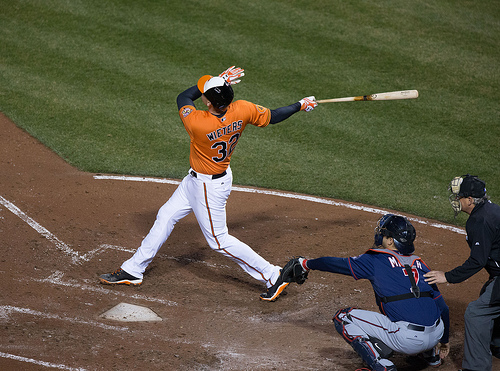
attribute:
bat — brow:
[319, 90, 420, 105]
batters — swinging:
[101, 64, 318, 303]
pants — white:
[119, 168, 284, 290]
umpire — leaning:
[424, 174, 500, 369]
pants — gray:
[464, 277, 499, 370]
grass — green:
[0, 1, 499, 231]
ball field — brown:
[1, 109, 500, 363]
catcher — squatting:
[278, 214, 450, 369]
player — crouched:
[279, 213, 450, 369]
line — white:
[93, 173, 467, 238]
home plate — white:
[101, 301, 161, 324]